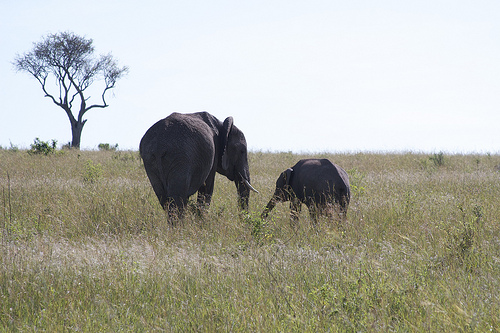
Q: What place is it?
A: It is a plain.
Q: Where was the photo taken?
A: It was taken at the plain.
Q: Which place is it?
A: It is a plain.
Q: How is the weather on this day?
A: It is clear.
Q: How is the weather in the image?
A: It is clear.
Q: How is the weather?
A: It is clear.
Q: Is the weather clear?
A: Yes, it is clear.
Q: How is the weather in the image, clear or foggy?
A: It is clear.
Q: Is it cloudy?
A: No, it is clear.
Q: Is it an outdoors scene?
A: Yes, it is outdoors.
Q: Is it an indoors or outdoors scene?
A: It is outdoors.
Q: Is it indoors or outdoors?
A: It is outdoors.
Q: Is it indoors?
A: No, it is outdoors.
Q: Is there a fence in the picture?
A: No, there are no fences.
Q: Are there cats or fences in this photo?
A: No, there are no fences or cats.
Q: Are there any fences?
A: No, there are no fences.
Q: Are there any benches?
A: No, there are no benches.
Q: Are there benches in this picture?
A: No, there are no benches.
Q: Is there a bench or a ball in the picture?
A: No, there are no benches or balls.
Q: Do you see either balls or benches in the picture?
A: No, there are no benches or balls.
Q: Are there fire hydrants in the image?
A: No, there are no fire hydrants.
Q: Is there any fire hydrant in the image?
A: No, there are no fire hydrants.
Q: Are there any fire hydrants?
A: No, there are no fire hydrants.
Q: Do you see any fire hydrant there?
A: No, there are no fire hydrants.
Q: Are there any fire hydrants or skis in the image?
A: No, there are no fire hydrants or skis.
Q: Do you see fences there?
A: No, there are no fences.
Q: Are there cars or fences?
A: No, there are no fences or cars.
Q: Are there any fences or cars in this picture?
A: No, there are no fences or cars.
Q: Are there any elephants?
A: Yes, there is an elephant.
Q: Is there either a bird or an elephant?
A: Yes, there is an elephant.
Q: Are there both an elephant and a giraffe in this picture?
A: No, there is an elephant but no giraffes.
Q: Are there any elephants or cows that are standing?
A: Yes, the elephant is standing.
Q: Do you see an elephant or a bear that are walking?
A: Yes, the elephant is walking.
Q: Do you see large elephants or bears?
A: Yes, there is a large elephant.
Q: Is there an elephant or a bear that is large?
A: Yes, the elephant is large.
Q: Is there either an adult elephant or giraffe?
A: Yes, there is an adult elephant.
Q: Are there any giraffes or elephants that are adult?
A: Yes, the elephant is adult.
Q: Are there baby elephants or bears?
A: Yes, there is a baby elephant.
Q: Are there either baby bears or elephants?
A: Yes, there is a baby elephant.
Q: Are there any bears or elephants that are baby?
A: Yes, the elephant is a baby.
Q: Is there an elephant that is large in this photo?
A: Yes, there is a large elephant.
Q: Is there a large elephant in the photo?
A: Yes, there is a large elephant.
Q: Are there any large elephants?
A: Yes, there is a large elephant.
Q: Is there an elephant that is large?
A: Yes, there is an elephant that is large.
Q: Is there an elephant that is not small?
A: Yes, there is a large elephant.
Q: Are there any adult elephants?
A: Yes, there is an adult elephant.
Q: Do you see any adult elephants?
A: Yes, there is an adult elephant.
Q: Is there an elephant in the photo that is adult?
A: Yes, there is an elephant that is adult.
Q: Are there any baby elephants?
A: Yes, there is a baby elephant.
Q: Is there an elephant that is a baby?
A: Yes, there is an elephant that is a baby.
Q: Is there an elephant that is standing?
A: Yes, there is an elephant that is standing.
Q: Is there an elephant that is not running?
A: Yes, there is an elephant that is standing.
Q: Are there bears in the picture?
A: No, there are no bears.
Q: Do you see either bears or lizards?
A: No, there are no bears or lizards.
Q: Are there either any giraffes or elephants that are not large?
A: No, there is an elephant but it is large.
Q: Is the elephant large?
A: Yes, the elephant is large.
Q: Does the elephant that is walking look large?
A: Yes, the elephant is large.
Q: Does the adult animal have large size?
A: Yes, the elephant is large.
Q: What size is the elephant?
A: The elephant is large.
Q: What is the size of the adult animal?
A: The elephant is large.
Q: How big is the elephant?
A: The elephant is large.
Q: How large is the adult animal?
A: The elephant is large.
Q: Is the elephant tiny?
A: No, the elephant is large.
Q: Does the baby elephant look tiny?
A: No, the elephant is large.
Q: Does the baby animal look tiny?
A: No, the elephant is large.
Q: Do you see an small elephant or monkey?
A: No, there is an elephant but it is large.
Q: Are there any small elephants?
A: No, there is an elephant but it is large.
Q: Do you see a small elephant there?
A: No, there is an elephant but it is large.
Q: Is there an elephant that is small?
A: No, there is an elephant but it is large.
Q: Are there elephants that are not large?
A: No, there is an elephant but it is large.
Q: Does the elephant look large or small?
A: The elephant is large.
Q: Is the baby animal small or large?
A: The elephant is large.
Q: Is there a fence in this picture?
A: No, there are no fences.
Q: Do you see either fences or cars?
A: No, there are no fences or cars.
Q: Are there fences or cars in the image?
A: No, there are no fences or cars.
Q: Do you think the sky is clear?
A: Yes, the sky is clear.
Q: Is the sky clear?
A: Yes, the sky is clear.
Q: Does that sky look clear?
A: Yes, the sky is clear.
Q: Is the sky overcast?
A: No, the sky is clear.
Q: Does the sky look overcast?
A: No, the sky is clear.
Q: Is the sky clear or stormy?
A: The sky is clear.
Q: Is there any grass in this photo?
A: Yes, there is grass.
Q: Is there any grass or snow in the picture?
A: Yes, there is grass.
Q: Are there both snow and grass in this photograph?
A: No, there is grass but no snow.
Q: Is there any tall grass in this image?
A: Yes, there is tall grass.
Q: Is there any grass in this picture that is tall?
A: Yes, there is grass that is tall.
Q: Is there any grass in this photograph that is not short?
A: Yes, there is tall grass.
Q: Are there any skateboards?
A: No, there are no skateboards.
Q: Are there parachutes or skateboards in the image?
A: No, there are no skateboards or parachutes.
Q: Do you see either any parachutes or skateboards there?
A: No, there are no skateboards or parachutes.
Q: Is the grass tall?
A: Yes, the grass is tall.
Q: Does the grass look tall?
A: Yes, the grass is tall.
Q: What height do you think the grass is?
A: The grass is tall.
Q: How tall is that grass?
A: The grass is tall.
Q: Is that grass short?
A: No, the grass is tall.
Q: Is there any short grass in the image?
A: No, there is grass but it is tall.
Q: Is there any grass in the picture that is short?
A: No, there is grass but it is tall.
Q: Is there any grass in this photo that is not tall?
A: No, there is grass but it is tall.